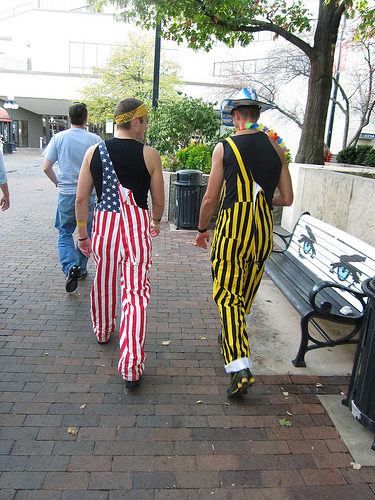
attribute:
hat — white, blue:
[216, 83, 277, 129]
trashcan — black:
[171, 167, 208, 232]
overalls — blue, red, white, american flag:
[87, 136, 153, 383]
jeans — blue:
[54, 192, 97, 294]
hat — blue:
[219, 85, 269, 107]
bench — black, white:
[271, 192, 371, 378]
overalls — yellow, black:
[216, 138, 274, 369]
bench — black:
[281, 197, 366, 308]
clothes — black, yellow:
[208, 134, 281, 367]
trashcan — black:
[143, 167, 218, 229]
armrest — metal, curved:
[307, 280, 367, 314]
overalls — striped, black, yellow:
[208, 139, 278, 373]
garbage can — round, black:
[160, 169, 198, 229]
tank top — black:
[88, 137, 151, 207]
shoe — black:
[57, 264, 93, 308]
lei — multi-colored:
[233, 121, 292, 163]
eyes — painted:
[292, 215, 365, 287]